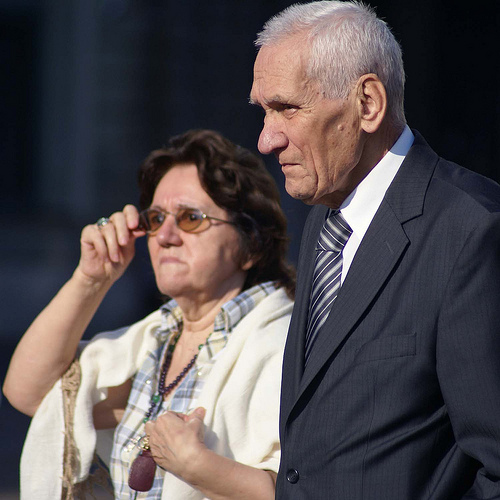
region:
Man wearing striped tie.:
[300, 225, 337, 295]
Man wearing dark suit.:
[342, 251, 424, 386]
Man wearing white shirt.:
[348, 198, 377, 248]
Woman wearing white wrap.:
[231, 362, 256, 416]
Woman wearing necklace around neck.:
[131, 349, 197, 381]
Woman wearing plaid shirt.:
[112, 389, 182, 489]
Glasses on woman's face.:
[131, 205, 242, 257]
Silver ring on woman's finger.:
[90, 210, 127, 254]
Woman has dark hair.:
[219, 156, 283, 266]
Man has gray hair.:
[334, 9, 405, 77]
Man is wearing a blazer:
[270, 135, 497, 499]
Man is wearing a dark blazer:
[275, 132, 497, 497]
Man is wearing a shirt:
[299, 120, 412, 357]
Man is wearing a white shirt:
[302, 120, 418, 287]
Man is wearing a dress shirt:
[328, 118, 415, 288]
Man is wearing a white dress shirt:
[337, 118, 419, 295]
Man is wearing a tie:
[299, 202, 353, 371]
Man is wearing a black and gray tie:
[299, 195, 356, 383]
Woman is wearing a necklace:
[124, 303, 234, 495]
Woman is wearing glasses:
[135, 201, 239, 236]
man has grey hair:
[264, 10, 447, 170]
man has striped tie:
[310, 211, 359, 314]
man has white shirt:
[279, 94, 420, 337]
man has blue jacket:
[278, 167, 464, 499]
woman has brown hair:
[103, 128, 315, 263]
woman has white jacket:
[69, 280, 315, 497]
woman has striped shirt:
[102, 314, 278, 475]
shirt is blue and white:
[106, 283, 246, 479]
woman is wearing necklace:
[156, 303, 241, 415]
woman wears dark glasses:
[129, 192, 261, 258]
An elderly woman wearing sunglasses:
[2, 129, 295, 499]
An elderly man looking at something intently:
[249, 0, 499, 497]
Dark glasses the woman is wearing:
[140, 204, 242, 233]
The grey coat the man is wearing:
[275, 131, 497, 498]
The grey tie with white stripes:
[305, 211, 352, 360]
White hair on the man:
[256, 0, 403, 128]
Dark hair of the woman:
[137, 129, 294, 298]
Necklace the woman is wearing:
[142, 320, 218, 421]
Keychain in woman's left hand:
[127, 435, 154, 490]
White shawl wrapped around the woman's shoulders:
[18, 287, 294, 499]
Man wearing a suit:
[243, 1, 497, 498]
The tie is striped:
[295, 207, 359, 369]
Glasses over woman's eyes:
[130, 199, 245, 241]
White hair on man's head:
[243, 2, 413, 207]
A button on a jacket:
[278, 457, 308, 495]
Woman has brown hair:
[128, 124, 303, 308]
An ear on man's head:
[345, 65, 395, 139]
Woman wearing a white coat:
[2, 121, 294, 498]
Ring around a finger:
[86, 204, 121, 234]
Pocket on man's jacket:
[340, 322, 425, 394]